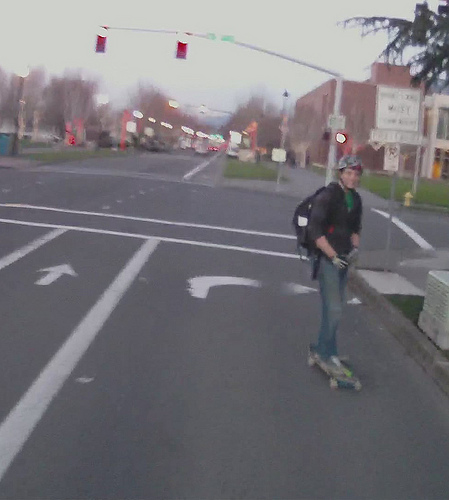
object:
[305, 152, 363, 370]
man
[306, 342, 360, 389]
skateboard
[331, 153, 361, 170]
helmet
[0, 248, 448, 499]
road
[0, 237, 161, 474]
strip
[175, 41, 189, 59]
light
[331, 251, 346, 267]
glove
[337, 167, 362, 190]
face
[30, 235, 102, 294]
srrow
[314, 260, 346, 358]
jeans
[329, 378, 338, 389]
wheel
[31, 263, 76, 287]
arrow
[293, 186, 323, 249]
backpack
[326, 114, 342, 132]
sign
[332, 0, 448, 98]
tree